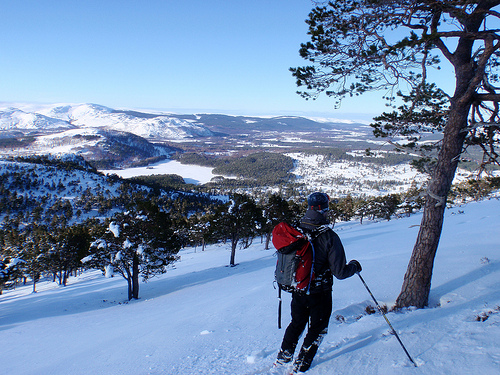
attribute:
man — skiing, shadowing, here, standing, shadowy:
[268, 183, 367, 374]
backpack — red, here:
[270, 219, 315, 298]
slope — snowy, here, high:
[1, 203, 500, 372]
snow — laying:
[3, 98, 500, 371]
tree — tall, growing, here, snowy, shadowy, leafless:
[298, 0, 499, 319]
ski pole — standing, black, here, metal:
[356, 266, 434, 373]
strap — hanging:
[274, 285, 286, 329]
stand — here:
[358, 205, 470, 240]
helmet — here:
[308, 190, 332, 210]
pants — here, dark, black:
[279, 288, 335, 369]